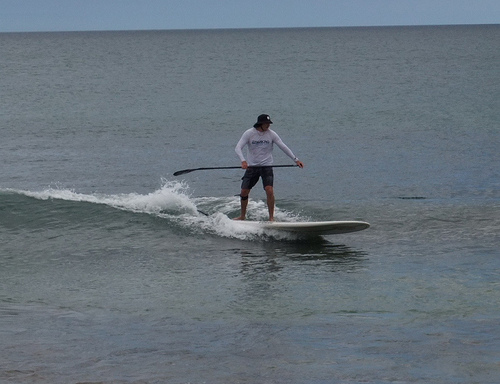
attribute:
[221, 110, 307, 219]
person — surfing, standing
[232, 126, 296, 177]
shirt — white, long sleeved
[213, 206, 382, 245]
paddleboard — white, large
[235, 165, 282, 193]
shorts — black, dark, colored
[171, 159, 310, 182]
oar — black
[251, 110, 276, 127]
hat — black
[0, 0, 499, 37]
sky — dark, blue